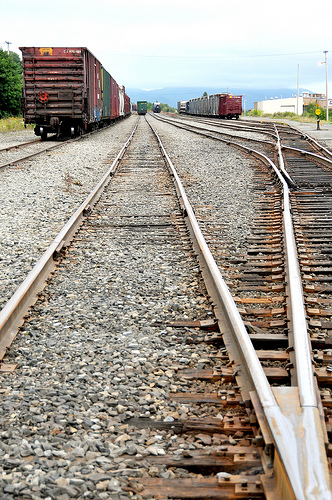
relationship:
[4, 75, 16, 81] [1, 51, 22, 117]
leaf on plant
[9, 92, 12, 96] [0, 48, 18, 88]
leaf on plant